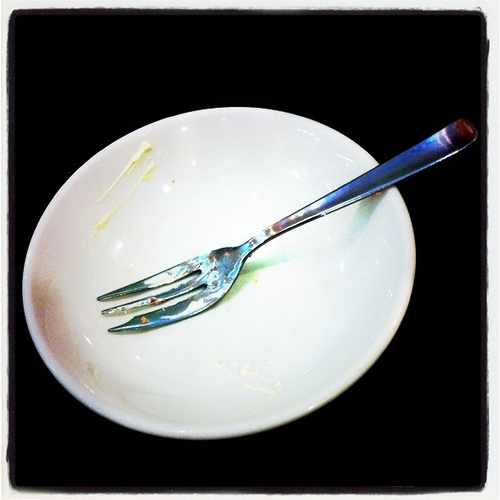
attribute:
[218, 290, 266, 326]
plate — white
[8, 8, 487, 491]
table cloth — black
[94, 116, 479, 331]
fork — silver, dirty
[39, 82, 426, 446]
plate — white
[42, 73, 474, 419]
fork — dirty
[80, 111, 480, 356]
fork — dirty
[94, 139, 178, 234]
cream — yellow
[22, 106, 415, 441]
plate — white, empty, not clean, dirty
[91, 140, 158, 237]
things — eatable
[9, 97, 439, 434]
plate — white, round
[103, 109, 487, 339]
fork — silver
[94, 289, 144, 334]
parts — three, pointed